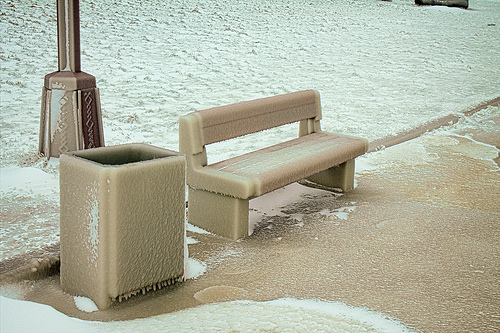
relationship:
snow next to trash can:
[0, 294, 104, 332] [59, 143, 186, 306]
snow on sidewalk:
[0, 294, 104, 332] [0, 104, 499, 332]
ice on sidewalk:
[1, 117, 500, 332] [0, 104, 499, 332]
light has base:
[38, 1, 105, 160] [38, 71, 105, 160]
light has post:
[38, 1, 105, 160] [56, 1, 81, 70]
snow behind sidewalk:
[0, 0, 499, 256] [0, 104, 499, 332]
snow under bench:
[240, 179, 345, 235] [178, 89, 369, 240]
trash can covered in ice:
[59, 143, 186, 306] [1, 117, 500, 332]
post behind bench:
[56, 1, 81, 70] [178, 89, 369, 240]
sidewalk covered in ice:
[0, 104, 499, 332] [1, 117, 500, 332]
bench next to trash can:
[178, 89, 369, 240] [59, 143, 186, 306]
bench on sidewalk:
[178, 89, 369, 240] [0, 104, 499, 332]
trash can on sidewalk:
[59, 143, 186, 306] [0, 104, 499, 332]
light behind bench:
[38, 1, 105, 160] [178, 89, 369, 240]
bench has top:
[178, 89, 369, 240] [179, 88, 321, 155]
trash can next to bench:
[59, 143, 186, 306] [178, 89, 369, 240]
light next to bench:
[38, 1, 105, 160] [178, 89, 369, 240]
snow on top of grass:
[0, 0, 499, 256] [0, 0, 500, 261]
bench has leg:
[178, 89, 369, 240] [186, 186, 249, 240]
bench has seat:
[178, 89, 369, 240] [186, 130, 368, 199]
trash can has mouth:
[59, 143, 186, 306] [76, 144, 174, 165]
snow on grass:
[0, 0, 499, 256] [0, 0, 500, 261]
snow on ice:
[240, 179, 345, 235] [1, 117, 500, 332]